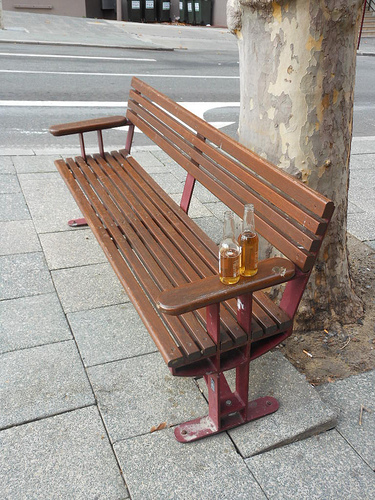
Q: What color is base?
A: Red.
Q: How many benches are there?
A: One.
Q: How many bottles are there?
A: Two.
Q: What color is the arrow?
A: White.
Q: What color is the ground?
A: Grey.